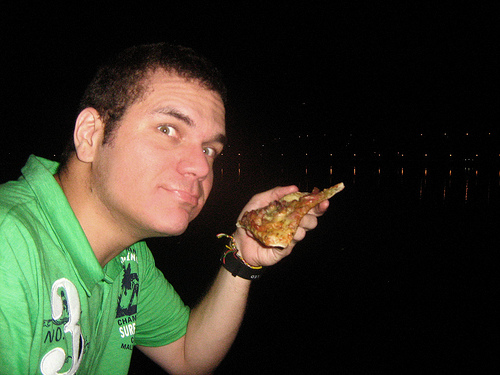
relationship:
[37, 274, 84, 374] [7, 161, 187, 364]
3 on shirt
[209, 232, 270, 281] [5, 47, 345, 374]
bracelet worn by man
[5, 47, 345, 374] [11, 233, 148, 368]
man wearing shirt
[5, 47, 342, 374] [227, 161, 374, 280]
man holds pizza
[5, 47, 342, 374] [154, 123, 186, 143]
man has eye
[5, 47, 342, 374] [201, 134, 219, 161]
man has eye